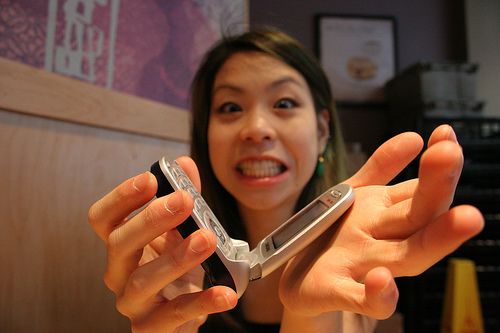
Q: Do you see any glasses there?
A: No, there are no glasses.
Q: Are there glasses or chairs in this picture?
A: No, there are no glasses or chairs.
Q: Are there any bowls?
A: No, there are no bowls.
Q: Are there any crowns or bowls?
A: No, there are no bowls or crowns.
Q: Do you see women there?
A: Yes, there is a woman.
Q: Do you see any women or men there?
A: Yes, there is a woman.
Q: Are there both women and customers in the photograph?
A: No, there is a woman but no customers.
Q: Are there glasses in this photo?
A: No, there are no glasses.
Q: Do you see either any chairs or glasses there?
A: No, there are no glasses or chairs.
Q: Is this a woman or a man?
A: This is a woman.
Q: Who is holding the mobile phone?
A: The woman is holding the mobile phone.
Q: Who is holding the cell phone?
A: The woman is holding the mobile phone.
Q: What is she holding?
A: The woman is holding the cellphone.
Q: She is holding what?
A: The woman is holding the cellphone.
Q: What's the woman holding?
A: The woman is holding the cellphone.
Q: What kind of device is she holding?
A: The woman is holding the mobile phone.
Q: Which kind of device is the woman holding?
A: The woman is holding the mobile phone.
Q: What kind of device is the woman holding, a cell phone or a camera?
A: The woman is holding a cell phone.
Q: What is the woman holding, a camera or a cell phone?
A: The woman is holding a cell phone.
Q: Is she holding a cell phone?
A: Yes, the woman is holding a cell phone.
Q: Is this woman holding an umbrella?
A: No, the woman is holding a cell phone.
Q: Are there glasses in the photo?
A: No, there are no glasses.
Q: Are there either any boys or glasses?
A: No, there are no glasses or boys.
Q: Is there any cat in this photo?
A: No, there are no cats.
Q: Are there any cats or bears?
A: No, there are no cats or bears.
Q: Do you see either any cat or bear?
A: No, there are no cats or bears.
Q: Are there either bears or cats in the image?
A: No, there are no cats or bears.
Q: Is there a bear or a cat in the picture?
A: No, there are no cats or bears.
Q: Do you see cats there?
A: No, there are no cats.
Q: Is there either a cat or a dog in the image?
A: No, there are no cats or dogs.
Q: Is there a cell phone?
A: Yes, there is a cell phone.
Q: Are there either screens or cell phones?
A: Yes, there is a cell phone.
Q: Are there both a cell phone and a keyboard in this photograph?
A: No, there is a cell phone but no keyboards.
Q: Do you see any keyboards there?
A: No, there are no keyboards.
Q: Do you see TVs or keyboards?
A: No, there are no keyboards or tvs.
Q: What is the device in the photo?
A: The device is a cell phone.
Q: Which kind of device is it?
A: The device is a cell phone.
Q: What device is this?
A: This is a cell phone.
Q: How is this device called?
A: This is a cell phone.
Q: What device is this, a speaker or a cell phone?
A: This is a cell phone.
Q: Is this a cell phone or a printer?
A: This is a cell phone.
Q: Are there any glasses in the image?
A: No, there are no glasses.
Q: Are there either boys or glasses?
A: No, there are no glasses or boys.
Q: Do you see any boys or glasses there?
A: No, there are no glasses or boys.